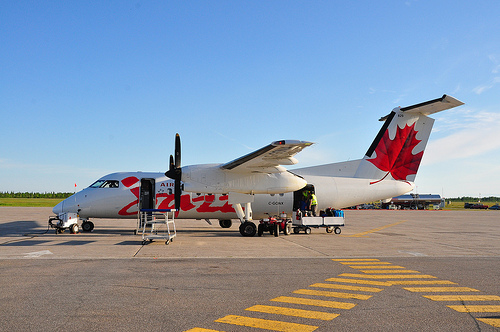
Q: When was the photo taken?
A: Daytime.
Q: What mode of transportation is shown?
A: Plane.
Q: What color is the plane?
A: White and red.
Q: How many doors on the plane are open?
A: Two.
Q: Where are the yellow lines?
A: Pavement.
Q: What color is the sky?
A: Blue.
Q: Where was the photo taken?
A: At an airport.